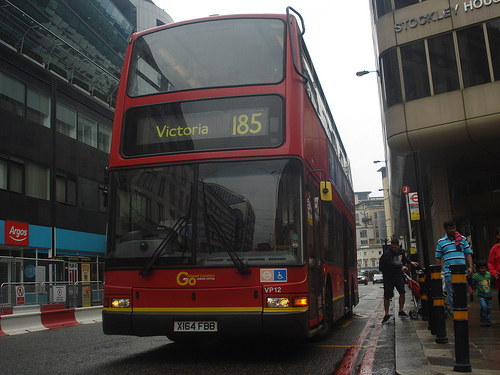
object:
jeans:
[477, 295, 493, 323]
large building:
[0, 0, 500, 372]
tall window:
[377, 47, 404, 112]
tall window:
[400, 40, 432, 101]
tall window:
[427, 32, 461, 95]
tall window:
[456, 23, 493, 88]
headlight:
[266, 296, 289, 307]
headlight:
[111, 297, 130, 308]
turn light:
[292, 297, 308, 307]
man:
[435, 221, 474, 316]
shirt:
[435, 233, 473, 277]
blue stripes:
[441, 251, 465, 260]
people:
[379, 220, 498, 327]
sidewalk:
[394, 284, 498, 375]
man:
[379, 238, 419, 323]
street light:
[355, 70, 394, 227]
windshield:
[107, 157, 303, 268]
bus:
[102, 6, 360, 342]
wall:
[0, 3, 174, 317]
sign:
[156, 124, 208, 138]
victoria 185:
[232, 113, 262, 135]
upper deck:
[108, 85, 303, 169]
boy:
[470, 259, 497, 326]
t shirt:
[472, 271, 494, 297]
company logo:
[4, 220, 29, 246]